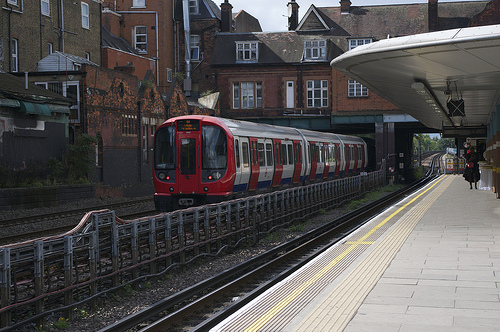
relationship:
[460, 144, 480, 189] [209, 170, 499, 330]
passenger waiting on platform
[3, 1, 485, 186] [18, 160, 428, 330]
buildings around tracks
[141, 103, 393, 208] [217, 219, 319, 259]
train by tracks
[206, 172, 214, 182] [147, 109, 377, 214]
headlight by on train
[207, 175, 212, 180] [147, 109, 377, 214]
red light on train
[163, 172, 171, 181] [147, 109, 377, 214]
red light on train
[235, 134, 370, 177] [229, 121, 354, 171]
doors on train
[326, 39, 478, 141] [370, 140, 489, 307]
roof over waiting area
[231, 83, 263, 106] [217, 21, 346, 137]
window on side building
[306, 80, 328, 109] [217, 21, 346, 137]
window on side building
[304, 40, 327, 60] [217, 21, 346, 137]
window on side building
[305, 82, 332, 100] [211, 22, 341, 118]
window on side building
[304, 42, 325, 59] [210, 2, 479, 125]
window on side building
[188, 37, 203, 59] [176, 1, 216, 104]
window on side building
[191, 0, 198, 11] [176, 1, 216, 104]
window on side building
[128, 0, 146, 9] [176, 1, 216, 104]
window on side building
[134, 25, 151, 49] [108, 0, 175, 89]
window on side building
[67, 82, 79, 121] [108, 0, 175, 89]
window on side building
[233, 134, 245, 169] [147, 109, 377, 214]
window on side train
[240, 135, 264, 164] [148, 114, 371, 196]
window on side train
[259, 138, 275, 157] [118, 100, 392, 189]
window on side train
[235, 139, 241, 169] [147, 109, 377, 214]
window on side train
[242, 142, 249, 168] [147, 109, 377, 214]
window on side train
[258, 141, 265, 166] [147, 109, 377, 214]
window on side train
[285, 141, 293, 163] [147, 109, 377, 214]
window on side train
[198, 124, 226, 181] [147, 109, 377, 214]
window on side train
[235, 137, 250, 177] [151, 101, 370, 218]
window on side train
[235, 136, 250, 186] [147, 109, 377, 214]
door on train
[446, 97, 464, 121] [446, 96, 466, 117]
t on sign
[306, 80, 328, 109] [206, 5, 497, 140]
window on building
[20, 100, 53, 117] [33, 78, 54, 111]
canopy over window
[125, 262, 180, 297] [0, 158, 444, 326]
gravel between train tracks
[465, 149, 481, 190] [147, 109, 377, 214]
person waiting for train